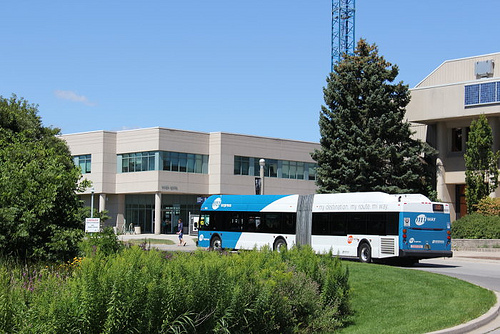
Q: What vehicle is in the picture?
A: A bus.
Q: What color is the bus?
A: White and blue.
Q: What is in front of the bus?
A: A building.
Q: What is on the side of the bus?
A: A tree.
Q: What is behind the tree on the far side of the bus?
A: Radio tower.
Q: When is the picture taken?
A: Daytime.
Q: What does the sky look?
A: Clear.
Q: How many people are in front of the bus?
A: One.